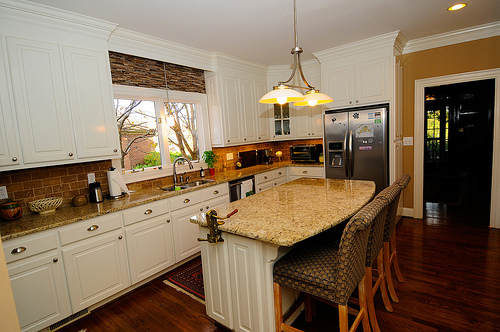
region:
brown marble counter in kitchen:
[210, 173, 351, 224]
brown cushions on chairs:
[299, 185, 417, 295]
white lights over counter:
[265, 52, 324, 117]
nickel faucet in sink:
[165, 156, 187, 193]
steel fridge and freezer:
[319, 110, 385, 180]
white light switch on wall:
[395, 126, 415, 150]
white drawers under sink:
[0, 177, 222, 294]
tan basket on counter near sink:
[32, 186, 63, 218]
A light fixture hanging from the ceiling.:
[258, 0, 333, 107]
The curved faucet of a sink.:
[171, 155, 193, 184]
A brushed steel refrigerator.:
[323, 105, 389, 178]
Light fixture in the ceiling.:
[446, 0, 467, 12]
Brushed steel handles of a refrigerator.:
[342, 128, 353, 179]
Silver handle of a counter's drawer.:
[58, 213, 123, 248]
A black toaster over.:
[288, 142, 324, 164]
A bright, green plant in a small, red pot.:
[203, 148, 218, 176]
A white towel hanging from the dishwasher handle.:
[239, 176, 254, 197]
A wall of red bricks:
[25, 170, 61, 192]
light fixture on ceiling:
[430, 0, 464, 16]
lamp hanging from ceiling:
[262, 0, 331, 112]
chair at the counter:
[278, 198, 390, 330]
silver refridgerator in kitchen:
[325, 107, 387, 181]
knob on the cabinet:
[116, 232, 129, 239]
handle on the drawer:
[86, 216, 101, 239]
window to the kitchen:
[120, 98, 164, 172]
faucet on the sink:
[170, 159, 195, 185]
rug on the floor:
[166, 251, 205, 300]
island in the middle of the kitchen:
[183, 161, 401, 330]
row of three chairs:
[275, 170, 425, 327]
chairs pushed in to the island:
[188, 158, 430, 330]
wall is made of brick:
[3, 156, 127, 219]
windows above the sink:
[115, 88, 230, 197]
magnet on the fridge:
[351, 108, 364, 120]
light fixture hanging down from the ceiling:
[259, 2, 335, 117]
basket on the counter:
[27, 191, 65, 218]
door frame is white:
[408, 64, 499, 229]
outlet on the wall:
[224, 150, 235, 163]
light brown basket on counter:
[23, 191, 64, 216]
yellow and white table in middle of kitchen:
[186, 172, 384, 251]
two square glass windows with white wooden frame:
[103, 80, 217, 191]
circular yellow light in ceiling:
[443, 0, 467, 14]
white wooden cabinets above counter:
[0, 1, 127, 176]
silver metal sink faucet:
[169, 154, 194, 184]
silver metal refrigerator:
[318, 100, 392, 244]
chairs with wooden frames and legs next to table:
[268, 165, 408, 330]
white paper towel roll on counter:
[103, 163, 132, 203]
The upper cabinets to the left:
[1, 5, 133, 173]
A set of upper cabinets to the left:
[1, 5, 147, 177]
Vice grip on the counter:
[193, 200, 238, 252]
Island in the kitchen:
[166, 172, 390, 320]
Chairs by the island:
[288, 172, 419, 315]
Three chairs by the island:
[284, 178, 413, 314]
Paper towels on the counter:
[98, 160, 133, 200]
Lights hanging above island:
[253, 71, 339, 116]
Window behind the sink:
[103, 80, 215, 173]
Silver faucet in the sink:
[151, 153, 199, 188]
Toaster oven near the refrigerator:
[285, 140, 321, 165]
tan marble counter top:
[195, 143, 377, 261]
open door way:
[410, 59, 492, 229]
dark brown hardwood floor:
[17, 211, 499, 326]